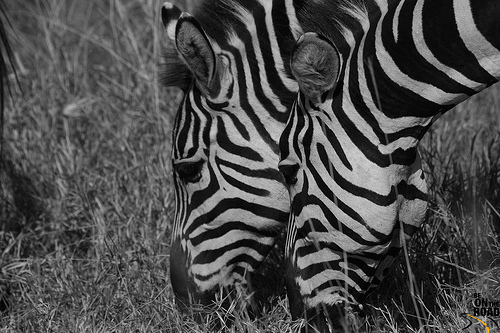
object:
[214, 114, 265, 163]
stripes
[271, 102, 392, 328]
face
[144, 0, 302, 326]
mother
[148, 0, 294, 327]
heads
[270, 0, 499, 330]
zebra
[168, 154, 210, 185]
eyes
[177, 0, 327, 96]
neck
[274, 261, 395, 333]
mouths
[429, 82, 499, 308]
grass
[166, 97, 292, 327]
face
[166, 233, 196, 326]
nose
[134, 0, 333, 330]
zebra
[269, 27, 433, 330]
head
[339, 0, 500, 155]
neck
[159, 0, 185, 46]
ear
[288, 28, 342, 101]
ear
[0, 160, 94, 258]
black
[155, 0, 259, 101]
mane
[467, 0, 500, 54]
stripes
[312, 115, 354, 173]
stripes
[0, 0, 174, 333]
grass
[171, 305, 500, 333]
grass